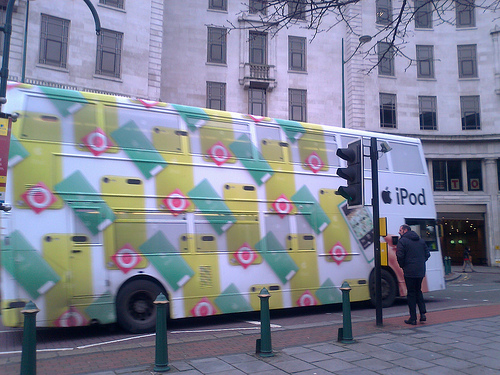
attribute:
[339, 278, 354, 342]
post — green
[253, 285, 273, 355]
post — green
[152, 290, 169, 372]
post — green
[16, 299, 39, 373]
post — green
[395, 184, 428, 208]
ipod logo — dark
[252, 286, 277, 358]
post — green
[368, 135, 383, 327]
pole — black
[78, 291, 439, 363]
pillars — green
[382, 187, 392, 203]
logo — apple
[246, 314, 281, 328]
line — white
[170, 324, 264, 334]
line — white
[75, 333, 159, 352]
line — white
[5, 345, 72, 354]
line — white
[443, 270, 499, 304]
gray road — grey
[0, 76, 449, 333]
bus — stopped, huge, white, double decker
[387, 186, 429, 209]
lettering — black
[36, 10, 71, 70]
window — closed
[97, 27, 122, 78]
window — closed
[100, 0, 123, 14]
window — closed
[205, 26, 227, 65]
window — closed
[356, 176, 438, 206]
logo — printed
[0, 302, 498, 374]
sidewalk — red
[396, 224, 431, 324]
man — standing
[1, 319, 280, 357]
lines — white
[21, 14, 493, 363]
building — white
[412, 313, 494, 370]
concrete — dark grey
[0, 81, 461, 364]
bus — double decker